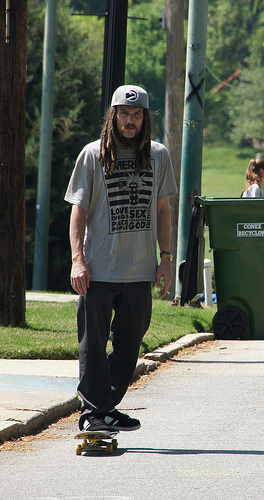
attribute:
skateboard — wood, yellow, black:
[74, 428, 119, 460]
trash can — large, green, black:
[179, 194, 262, 343]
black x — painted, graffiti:
[186, 70, 212, 114]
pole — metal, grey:
[175, 3, 207, 306]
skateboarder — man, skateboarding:
[64, 82, 177, 433]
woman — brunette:
[241, 155, 264, 198]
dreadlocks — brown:
[99, 105, 157, 174]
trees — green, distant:
[26, 3, 263, 289]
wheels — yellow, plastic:
[74, 441, 120, 455]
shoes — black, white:
[83, 412, 144, 433]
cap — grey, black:
[110, 84, 149, 115]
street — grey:
[8, 337, 264, 499]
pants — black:
[80, 283, 153, 417]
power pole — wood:
[2, 3, 26, 328]